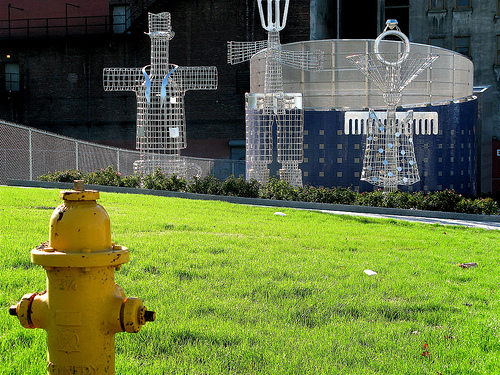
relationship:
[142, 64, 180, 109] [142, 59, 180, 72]
tie around neck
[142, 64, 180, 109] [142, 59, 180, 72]
scarf around neck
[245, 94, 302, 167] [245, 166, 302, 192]
trousers are above shoes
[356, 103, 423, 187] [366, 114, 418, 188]
skirt has dots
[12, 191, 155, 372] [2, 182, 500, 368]
hydrant in area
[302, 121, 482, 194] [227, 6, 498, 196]
squares are on wall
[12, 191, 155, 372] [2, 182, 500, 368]
hydrant on lawn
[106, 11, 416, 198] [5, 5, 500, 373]
sculptures are in park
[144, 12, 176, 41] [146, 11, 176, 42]
hat on top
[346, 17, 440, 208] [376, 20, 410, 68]
sculpture has ring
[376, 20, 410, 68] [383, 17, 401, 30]
ring has diamond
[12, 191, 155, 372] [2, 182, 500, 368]
hydrant on grass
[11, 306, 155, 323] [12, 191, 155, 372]
bolts are on hydrant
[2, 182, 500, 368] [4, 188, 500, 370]
grass on slope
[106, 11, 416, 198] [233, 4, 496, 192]
statues in front of building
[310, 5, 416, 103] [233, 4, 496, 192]
windows are on building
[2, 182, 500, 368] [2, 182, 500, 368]
grass in field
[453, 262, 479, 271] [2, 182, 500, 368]
rock in field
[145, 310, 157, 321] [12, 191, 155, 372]
bolt on hydrant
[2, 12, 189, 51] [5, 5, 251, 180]
railing on building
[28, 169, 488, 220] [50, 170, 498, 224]
blooms are on bushes